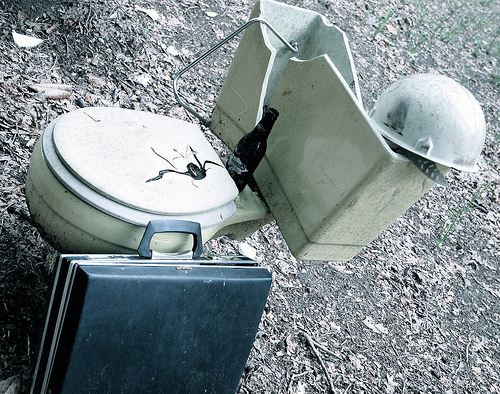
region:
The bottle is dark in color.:
[238, 106, 278, 183]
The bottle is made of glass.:
[234, 106, 280, 190]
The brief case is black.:
[28, 220, 279, 392]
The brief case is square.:
[26, 215, 261, 388]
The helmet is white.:
[371, 71, 488, 167]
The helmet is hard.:
[371, 73, 489, 172]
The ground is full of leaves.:
[347, 277, 474, 377]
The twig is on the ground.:
[298, 326, 340, 391]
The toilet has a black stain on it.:
[150, 149, 223, 185]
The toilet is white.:
[51, 120, 233, 208]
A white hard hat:
[369, 59, 499, 184]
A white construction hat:
[370, 61, 496, 176]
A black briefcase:
[35, 228, 272, 392]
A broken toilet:
[35, 1, 438, 268]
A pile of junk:
[14, 3, 483, 390]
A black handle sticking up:
[130, 212, 213, 267]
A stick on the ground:
[297, 324, 356, 392]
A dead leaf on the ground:
[31, 72, 75, 103]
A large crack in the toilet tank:
[255, 39, 285, 171]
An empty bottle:
[221, 106, 293, 193]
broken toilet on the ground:
[93, 20, 400, 285]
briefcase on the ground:
[58, 222, 263, 386]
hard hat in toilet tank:
[366, 65, 489, 172]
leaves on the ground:
[373, 320, 398, 337]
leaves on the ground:
[279, 362, 292, 381]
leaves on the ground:
[463, 268, 483, 285]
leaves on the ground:
[55, 80, 90, 96]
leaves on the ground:
[161, 45, 181, 60]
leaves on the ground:
[424, 45, 445, 67]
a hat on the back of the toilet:
[371, 70, 486, 198]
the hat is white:
[367, 74, 494, 180]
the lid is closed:
[51, 101, 235, 216]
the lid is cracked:
[134, 127, 233, 198]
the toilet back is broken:
[203, 0, 378, 234]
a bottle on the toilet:
[213, 90, 293, 202]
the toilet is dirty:
[20, 12, 442, 300]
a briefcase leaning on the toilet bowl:
[10, 204, 277, 386]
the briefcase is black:
[21, 212, 274, 383]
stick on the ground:
[282, 320, 392, 390]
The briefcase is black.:
[44, 235, 264, 392]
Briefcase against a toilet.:
[31, 77, 301, 392]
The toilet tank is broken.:
[205, 11, 390, 246]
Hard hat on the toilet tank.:
[375, 73, 490, 169]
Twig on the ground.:
[285, 321, 345, 392]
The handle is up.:
[133, 215, 214, 259]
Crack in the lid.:
[132, 127, 229, 199]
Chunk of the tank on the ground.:
[7, 25, 49, 60]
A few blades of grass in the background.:
[385, 9, 499, 63]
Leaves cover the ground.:
[18, 53, 473, 382]